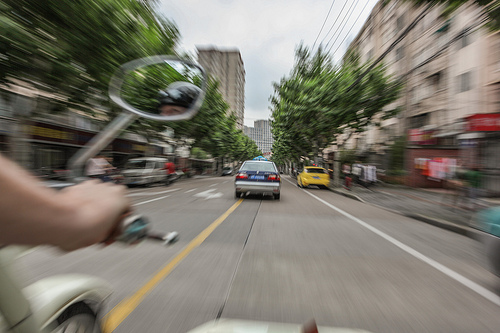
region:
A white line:
[350, 201, 439, 311]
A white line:
[391, 206, 418, 318]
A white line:
[390, 186, 447, 327]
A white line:
[409, 151, 463, 326]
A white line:
[319, 173, 425, 299]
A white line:
[373, 140, 438, 322]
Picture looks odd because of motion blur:
[18, 20, 462, 298]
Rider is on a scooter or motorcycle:
[17, 41, 225, 330]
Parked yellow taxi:
[288, 158, 339, 193]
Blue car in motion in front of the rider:
[233, 146, 288, 212]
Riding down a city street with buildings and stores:
[30, 7, 472, 167]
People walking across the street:
[51, 135, 186, 185]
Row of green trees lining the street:
[271, 38, 366, 193]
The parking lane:
[323, 167, 492, 297]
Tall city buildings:
[194, 16, 270, 152]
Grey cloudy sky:
[167, 3, 342, 92]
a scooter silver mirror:
[64, 56, 213, 179]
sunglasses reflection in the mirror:
[150, 82, 181, 98]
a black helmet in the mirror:
[162, 80, 197, 106]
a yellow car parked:
[298, 166, 331, 186]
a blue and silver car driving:
[232, 160, 278, 199]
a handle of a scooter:
[114, 209, 184, 251]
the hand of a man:
[60, 172, 132, 247]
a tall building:
[195, 46, 247, 123]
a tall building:
[243, 116, 276, 156]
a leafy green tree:
[274, 36, 384, 167]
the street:
[286, 211, 333, 298]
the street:
[285, 289, 312, 310]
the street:
[246, 248, 283, 284]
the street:
[259, 259, 289, 279]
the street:
[247, 182, 342, 309]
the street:
[251, 214, 306, 273]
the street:
[286, 227, 373, 310]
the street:
[271, 177, 328, 258]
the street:
[214, 150, 294, 224]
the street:
[193, 147, 296, 273]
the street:
[270, 228, 451, 325]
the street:
[250, 234, 328, 304]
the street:
[224, 241, 293, 292]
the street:
[241, 216, 285, 268]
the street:
[269, 243, 299, 285]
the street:
[214, 245, 254, 277]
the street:
[263, 236, 302, 267]